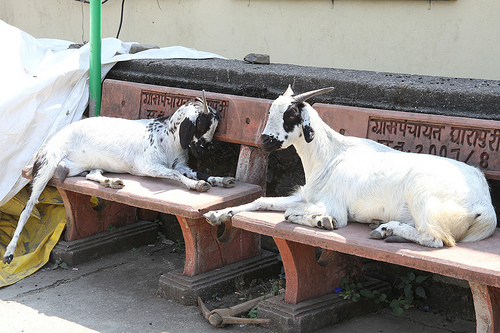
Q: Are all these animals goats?
A: Yes, all the animals are goats.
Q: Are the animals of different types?
A: No, all the animals are goats.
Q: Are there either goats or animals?
A: Yes, there are goats.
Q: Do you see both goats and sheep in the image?
A: No, there are goats but no sheep.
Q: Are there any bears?
A: No, there are no bears.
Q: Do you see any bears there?
A: No, there are no bears.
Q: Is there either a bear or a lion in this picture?
A: No, there are no bears or lions.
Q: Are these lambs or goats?
A: These are goats.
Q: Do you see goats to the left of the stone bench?
A: Yes, there are goats to the left of the bench.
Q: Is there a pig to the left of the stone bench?
A: No, there are goats to the left of the bench.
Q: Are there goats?
A: Yes, there are goats.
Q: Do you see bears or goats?
A: Yes, there are goats.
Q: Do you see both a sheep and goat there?
A: No, there are goats but no sheep.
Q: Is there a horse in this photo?
A: No, there are no horses.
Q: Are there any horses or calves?
A: No, there are no horses or calves.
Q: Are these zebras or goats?
A: These are goats.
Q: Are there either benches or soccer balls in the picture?
A: Yes, there is a bench.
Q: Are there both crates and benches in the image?
A: No, there is a bench but no crates.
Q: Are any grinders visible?
A: No, there are no grinders.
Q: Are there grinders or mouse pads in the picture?
A: No, there are no grinders or mouse pads.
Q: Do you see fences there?
A: No, there are no fences.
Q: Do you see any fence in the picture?
A: No, there are no fences.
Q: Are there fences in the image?
A: No, there are no fences.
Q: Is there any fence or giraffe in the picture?
A: No, there are no fences or giraffes.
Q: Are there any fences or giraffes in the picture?
A: No, there are no fences or giraffes.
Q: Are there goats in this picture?
A: Yes, there are goats.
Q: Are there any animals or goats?
A: Yes, there are goats.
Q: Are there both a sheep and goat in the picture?
A: No, there are goats but no sheep.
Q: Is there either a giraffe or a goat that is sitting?
A: Yes, the goats are sitting.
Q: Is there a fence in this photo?
A: No, there are no fences.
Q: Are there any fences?
A: No, there are no fences.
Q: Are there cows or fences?
A: No, there are no fences or cows.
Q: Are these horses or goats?
A: These are goats.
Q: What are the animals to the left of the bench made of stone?
A: The animals are goats.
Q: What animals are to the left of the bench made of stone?
A: The animals are goats.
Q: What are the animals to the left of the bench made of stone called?
A: The animals are goats.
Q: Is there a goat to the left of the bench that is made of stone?
A: Yes, there are goats to the left of the bench.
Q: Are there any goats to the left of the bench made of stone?
A: Yes, there are goats to the left of the bench.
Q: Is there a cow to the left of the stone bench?
A: No, there are goats to the left of the bench.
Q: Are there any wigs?
A: No, there are no wigs.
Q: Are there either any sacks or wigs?
A: No, there are no wigs or sacks.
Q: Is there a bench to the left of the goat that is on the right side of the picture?
A: Yes, there are benches to the left of the goat.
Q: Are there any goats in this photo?
A: Yes, there are goats.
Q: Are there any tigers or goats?
A: Yes, there are goats.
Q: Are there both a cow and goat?
A: No, there are goats but no cows.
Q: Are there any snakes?
A: No, there are no snakes.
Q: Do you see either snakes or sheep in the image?
A: No, there are no snakes or sheep.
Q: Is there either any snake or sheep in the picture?
A: No, there are no snakes or sheep.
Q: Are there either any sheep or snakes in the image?
A: No, there are no snakes or sheep.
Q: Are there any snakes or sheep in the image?
A: No, there are no snakes or sheep.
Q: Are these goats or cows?
A: These are goats.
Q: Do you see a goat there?
A: Yes, there are goats.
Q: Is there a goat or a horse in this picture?
A: Yes, there are goats.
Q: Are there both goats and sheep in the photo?
A: No, there are goats but no sheep.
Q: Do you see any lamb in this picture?
A: No, there are no lambs.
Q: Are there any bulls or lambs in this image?
A: No, there are no lambs or bulls.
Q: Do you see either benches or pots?
A: Yes, there is a bench.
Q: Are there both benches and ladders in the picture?
A: No, there is a bench but no ladders.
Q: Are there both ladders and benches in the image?
A: No, there is a bench but no ladders.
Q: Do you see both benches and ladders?
A: No, there is a bench but no ladders.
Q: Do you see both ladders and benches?
A: No, there is a bench but no ladders.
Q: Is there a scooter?
A: No, there are no scooters.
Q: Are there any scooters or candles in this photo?
A: No, there are no scooters or candles.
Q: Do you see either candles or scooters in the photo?
A: No, there are no scooters or candles.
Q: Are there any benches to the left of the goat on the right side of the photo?
A: Yes, there is a bench to the left of the goat.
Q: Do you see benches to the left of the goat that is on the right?
A: Yes, there is a bench to the left of the goat.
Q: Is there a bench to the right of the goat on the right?
A: No, the bench is to the left of the goat.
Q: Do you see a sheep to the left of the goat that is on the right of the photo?
A: No, there is a bench to the left of the goat.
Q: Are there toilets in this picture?
A: No, there are no toilets.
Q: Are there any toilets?
A: No, there are no toilets.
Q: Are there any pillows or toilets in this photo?
A: No, there are no toilets or pillows.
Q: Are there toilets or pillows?
A: No, there are no toilets or pillows.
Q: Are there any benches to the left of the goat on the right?
A: Yes, there are benches to the left of the goat.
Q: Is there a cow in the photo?
A: No, there are no cows.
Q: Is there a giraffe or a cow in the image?
A: No, there are no cows or giraffes.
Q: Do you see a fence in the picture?
A: No, there are no fences.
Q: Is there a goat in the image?
A: Yes, there is a goat.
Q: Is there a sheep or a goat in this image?
A: Yes, there is a goat.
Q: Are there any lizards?
A: No, there are no lizards.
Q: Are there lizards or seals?
A: No, there are no lizards or seals.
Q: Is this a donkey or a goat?
A: This is a goat.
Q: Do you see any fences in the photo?
A: No, there are no fences.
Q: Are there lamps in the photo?
A: No, there are no lamps.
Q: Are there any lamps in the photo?
A: No, there are no lamps.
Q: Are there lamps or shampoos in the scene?
A: No, there are no lamps or shampoos.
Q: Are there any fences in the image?
A: No, there are no fences.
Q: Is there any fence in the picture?
A: No, there are no fences.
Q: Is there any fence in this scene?
A: No, there are no fences.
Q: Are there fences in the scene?
A: No, there are no fences.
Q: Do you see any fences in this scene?
A: No, there are no fences.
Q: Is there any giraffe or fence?
A: No, there are no fences or giraffes.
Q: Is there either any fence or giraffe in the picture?
A: No, there are no fences or giraffes.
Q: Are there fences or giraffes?
A: No, there are no fences or giraffes.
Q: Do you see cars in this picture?
A: No, there are no cars.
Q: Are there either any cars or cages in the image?
A: No, there are no cars or cages.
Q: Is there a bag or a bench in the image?
A: Yes, there is a bench.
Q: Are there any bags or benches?
A: Yes, there is a bench.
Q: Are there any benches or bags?
A: Yes, there is a bench.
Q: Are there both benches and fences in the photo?
A: No, there is a bench but no fences.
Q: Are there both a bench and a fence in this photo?
A: No, there is a bench but no fences.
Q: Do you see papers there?
A: No, there are no papers.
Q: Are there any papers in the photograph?
A: No, there are no papers.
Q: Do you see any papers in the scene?
A: No, there are no papers.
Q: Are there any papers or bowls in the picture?
A: No, there are no papers or bowls.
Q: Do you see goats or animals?
A: Yes, there is a goat.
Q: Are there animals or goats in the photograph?
A: Yes, there is a goat.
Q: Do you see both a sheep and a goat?
A: No, there is a goat but no sheep.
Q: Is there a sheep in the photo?
A: No, there is no sheep.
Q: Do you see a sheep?
A: No, there is no sheep.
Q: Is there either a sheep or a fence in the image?
A: No, there are no sheep or fences.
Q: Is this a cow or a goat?
A: This is a goat.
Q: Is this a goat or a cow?
A: This is a goat.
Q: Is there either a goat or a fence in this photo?
A: Yes, there is a goat.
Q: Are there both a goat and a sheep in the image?
A: No, there is a goat but no sheep.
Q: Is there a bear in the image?
A: No, there are no bears.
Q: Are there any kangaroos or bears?
A: No, there are no bears or kangaroos.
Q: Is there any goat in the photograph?
A: Yes, there is a goat.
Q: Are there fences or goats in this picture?
A: Yes, there is a goat.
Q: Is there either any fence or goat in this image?
A: Yes, there is a goat.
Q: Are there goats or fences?
A: Yes, there is a goat.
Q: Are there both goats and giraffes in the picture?
A: No, there is a goat but no giraffes.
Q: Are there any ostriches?
A: No, there are no ostriches.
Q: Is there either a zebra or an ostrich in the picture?
A: No, there are no ostriches or zebras.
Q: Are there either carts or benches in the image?
A: Yes, there is a bench.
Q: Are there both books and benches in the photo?
A: No, there is a bench but no books.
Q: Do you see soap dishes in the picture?
A: No, there are no soap dishes.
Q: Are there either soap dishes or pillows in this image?
A: No, there are no soap dishes or pillows.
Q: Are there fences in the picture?
A: No, there are no fences.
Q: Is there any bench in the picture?
A: Yes, there is a bench.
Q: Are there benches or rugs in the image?
A: Yes, there is a bench.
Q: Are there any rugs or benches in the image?
A: Yes, there is a bench.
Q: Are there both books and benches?
A: No, there is a bench but no books.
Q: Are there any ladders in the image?
A: No, there are no ladders.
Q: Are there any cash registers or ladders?
A: No, there are no ladders or cash registers.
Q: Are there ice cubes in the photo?
A: No, there are no ice cubes.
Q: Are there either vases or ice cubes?
A: No, there are no ice cubes or vases.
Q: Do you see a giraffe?
A: No, there are no giraffes.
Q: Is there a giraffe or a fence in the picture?
A: No, there are no giraffes or fences.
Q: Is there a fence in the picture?
A: No, there are no fences.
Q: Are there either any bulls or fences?
A: No, there are no fences or bulls.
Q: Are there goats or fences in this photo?
A: Yes, there is a goat.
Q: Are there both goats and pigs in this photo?
A: No, there is a goat but no pigs.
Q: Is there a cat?
A: No, there are no cats.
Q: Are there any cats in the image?
A: No, there are no cats.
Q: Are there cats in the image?
A: No, there are no cats.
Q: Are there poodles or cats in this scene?
A: No, there are no cats or poodles.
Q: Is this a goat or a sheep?
A: This is a goat.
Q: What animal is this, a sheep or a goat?
A: This is a goat.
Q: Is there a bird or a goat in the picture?
A: Yes, there is a goat.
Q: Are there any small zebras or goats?
A: Yes, there is a small goat.